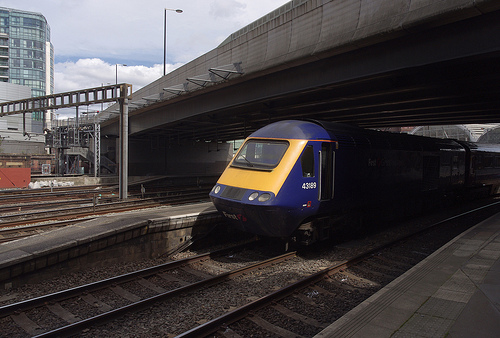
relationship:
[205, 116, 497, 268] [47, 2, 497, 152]
train sticking out under bridge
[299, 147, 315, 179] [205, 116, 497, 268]
window on train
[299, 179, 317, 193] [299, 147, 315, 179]
number under window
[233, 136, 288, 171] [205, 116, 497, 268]
windshield on train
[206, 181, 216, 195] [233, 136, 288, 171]
headlights under windshield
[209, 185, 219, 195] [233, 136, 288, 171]
headlights under windshield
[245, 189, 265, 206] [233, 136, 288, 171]
headlights under windshield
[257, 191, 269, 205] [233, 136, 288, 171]
headlights under windshield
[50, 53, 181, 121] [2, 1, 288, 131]
clouds fill sky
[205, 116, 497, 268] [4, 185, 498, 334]
train on tracks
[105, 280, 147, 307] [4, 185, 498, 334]
wood between tracks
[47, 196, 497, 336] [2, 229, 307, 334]
ballas between tracks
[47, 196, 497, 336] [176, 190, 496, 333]
ballas between tracks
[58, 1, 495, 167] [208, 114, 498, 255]
bridge over train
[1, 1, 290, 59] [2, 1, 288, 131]
clouds in sky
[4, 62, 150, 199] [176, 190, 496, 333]
tracks next to tracks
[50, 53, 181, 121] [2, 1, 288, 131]
clouds in sky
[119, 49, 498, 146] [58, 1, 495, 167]
underside of bridge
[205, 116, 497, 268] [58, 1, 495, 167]
train under bridge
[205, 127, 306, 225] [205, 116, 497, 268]
front on train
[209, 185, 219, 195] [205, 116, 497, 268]
headlights on train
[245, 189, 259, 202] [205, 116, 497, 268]
headlights on train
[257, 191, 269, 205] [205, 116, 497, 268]
headlights on train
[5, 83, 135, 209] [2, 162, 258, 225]
frame above tracks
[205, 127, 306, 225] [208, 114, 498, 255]
front on train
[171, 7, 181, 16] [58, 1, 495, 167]
light on bridge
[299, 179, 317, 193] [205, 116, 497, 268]
number on train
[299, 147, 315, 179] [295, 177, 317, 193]
window above number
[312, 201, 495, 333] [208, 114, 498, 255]
platform right of train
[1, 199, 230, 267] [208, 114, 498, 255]
walkway left of train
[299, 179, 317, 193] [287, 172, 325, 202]
number on background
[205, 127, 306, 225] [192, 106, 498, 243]
front on train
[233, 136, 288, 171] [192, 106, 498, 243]
windshield on train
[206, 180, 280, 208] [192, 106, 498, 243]
headlights on train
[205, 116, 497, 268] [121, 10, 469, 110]
train under a bridge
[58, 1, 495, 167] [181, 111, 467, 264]
bridge above train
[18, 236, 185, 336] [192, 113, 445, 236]
tracks of train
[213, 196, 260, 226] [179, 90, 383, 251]
part of train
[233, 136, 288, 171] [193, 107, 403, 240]
windshield of train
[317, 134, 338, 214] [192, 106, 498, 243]
door of train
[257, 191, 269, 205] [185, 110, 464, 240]
headlights of train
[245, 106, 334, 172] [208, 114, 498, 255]
top of train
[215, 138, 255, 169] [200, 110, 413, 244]
windshield wiper of train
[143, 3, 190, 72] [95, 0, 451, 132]
streetlight up on bridge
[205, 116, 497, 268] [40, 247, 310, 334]
train on tracks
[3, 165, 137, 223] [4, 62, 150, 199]
metal post over tracks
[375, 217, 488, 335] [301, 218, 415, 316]
platform next to tracks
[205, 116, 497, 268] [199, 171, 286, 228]
train has head lights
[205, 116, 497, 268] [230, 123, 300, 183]
train has winshield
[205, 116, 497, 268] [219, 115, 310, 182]
train has window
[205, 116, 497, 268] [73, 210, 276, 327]
train on track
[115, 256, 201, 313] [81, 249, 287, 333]
track on ground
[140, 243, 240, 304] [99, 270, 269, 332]
stones on ground